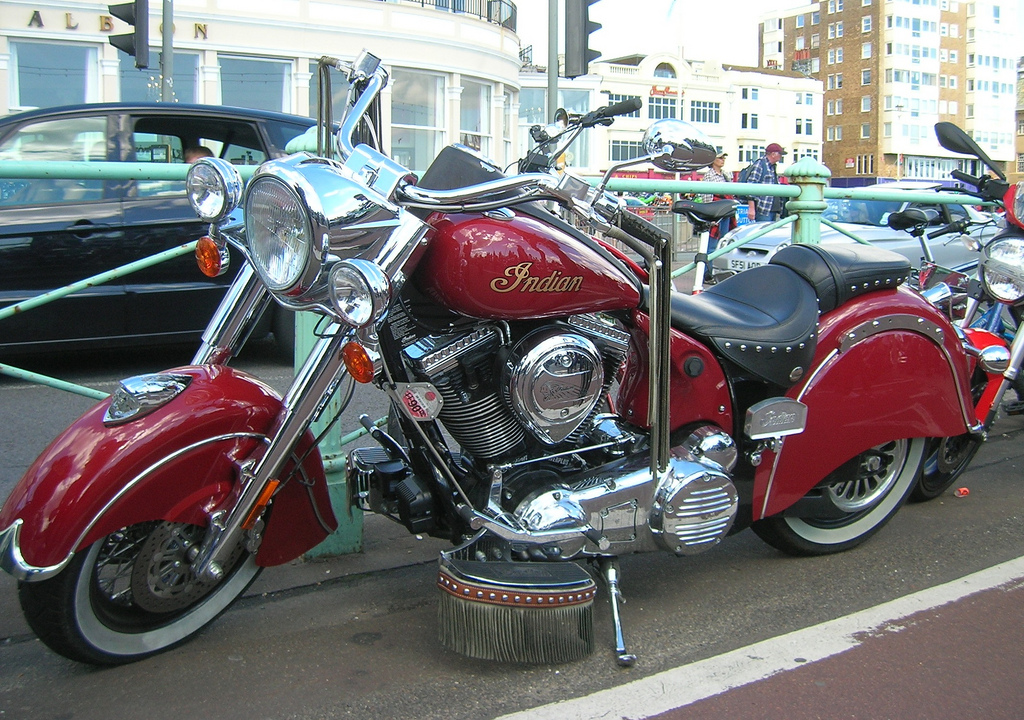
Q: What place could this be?
A: It is a pavement.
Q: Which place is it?
A: It is a pavement.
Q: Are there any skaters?
A: No, there are no skaters.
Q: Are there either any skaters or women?
A: No, there are no skaters or women.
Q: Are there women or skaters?
A: No, there are no skaters or women.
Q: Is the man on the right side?
A: Yes, the man is on the right of the image.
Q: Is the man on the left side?
A: No, the man is on the right of the image.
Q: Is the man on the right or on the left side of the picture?
A: The man is on the right of the image.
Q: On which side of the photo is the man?
A: The man is on the right of the image.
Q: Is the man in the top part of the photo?
A: Yes, the man is in the top of the image.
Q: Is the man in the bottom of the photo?
A: No, the man is in the top of the image.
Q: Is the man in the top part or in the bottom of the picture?
A: The man is in the top of the image.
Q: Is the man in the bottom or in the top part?
A: The man is in the top of the image.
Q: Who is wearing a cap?
A: The man is wearing a cap.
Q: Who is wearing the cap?
A: The man is wearing a cap.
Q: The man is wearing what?
A: The man is wearing a cap.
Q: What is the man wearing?
A: The man is wearing a cap.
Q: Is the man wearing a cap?
A: Yes, the man is wearing a cap.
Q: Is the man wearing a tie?
A: No, the man is wearing a cap.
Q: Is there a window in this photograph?
A: Yes, there is a window.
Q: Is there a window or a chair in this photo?
A: Yes, there is a window.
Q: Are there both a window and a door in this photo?
A: No, there is a window but no doors.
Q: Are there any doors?
A: No, there are no doors.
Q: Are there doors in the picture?
A: No, there are no doors.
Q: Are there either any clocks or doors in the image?
A: No, there are no doors or clocks.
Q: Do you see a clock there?
A: No, there are no clocks.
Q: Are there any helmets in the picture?
A: No, there are no helmets.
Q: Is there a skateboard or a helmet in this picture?
A: No, there are no helmets or skateboards.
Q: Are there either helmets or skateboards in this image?
A: No, there are no helmets or skateboards.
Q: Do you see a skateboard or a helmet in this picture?
A: No, there are no helmets or skateboards.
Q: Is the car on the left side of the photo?
A: Yes, the car is on the left of the image.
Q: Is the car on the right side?
A: No, the car is on the left of the image.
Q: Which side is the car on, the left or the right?
A: The car is on the left of the image.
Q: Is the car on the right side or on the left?
A: The car is on the left of the image.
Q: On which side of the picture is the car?
A: The car is on the left of the image.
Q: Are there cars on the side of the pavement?
A: Yes, there is a car on the side of the pavement.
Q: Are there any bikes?
A: Yes, there is a bike.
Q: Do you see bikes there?
A: Yes, there is a bike.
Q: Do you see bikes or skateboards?
A: Yes, there is a bike.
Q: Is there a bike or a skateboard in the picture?
A: Yes, there is a bike.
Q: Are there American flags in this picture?
A: No, there are no American flags.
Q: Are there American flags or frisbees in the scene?
A: No, there are no American flags or frisbees.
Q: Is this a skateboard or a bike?
A: This is a bike.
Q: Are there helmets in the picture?
A: No, there are no helmets.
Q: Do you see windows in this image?
A: Yes, there is a window.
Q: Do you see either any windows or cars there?
A: Yes, there is a window.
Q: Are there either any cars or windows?
A: Yes, there is a window.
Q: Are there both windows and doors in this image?
A: No, there is a window but no doors.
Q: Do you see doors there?
A: No, there are no doors.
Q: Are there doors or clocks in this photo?
A: No, there are no doors or clocks.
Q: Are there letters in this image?
A: Yes, there are letters.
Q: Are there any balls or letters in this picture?
A: Yes, there are letters.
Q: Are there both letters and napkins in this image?
A: No, there are letters but no napkins.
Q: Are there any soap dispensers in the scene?
A: No, there are no soap dispensers.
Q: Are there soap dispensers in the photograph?
A: No, there are no soap dispensers.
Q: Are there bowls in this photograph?
A: No, there are no bowls.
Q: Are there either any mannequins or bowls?
A: No, there are no bowls or mannequins.